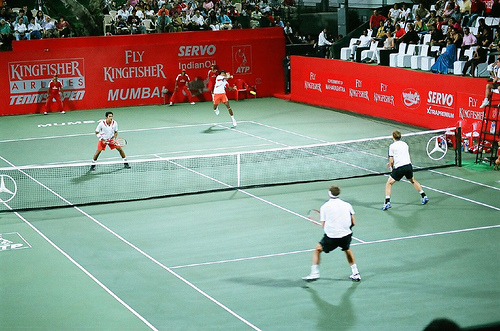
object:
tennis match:
[1, 38, 499, 327]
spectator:
[396, 24, 420, 50]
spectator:
[458, 43, 487, 78]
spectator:
[477, 18, 494, 46]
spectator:
[370, 10, 389, 35]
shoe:
[303, 265, 324, 285]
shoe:
[340, 263, 363, 282]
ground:
[392, 94, 472, 171]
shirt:
[93, 123, 120, 143]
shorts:
[321, 229, 356, 251]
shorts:
[391, 160, 416, 180]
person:
[191, 9, 209, 31]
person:
[207, 10, 220, 31]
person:
[156, 10, 171, 33]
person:
[250, 5, 263, 28]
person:
[56, 17, 70, 38]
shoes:
[298, 268, 362, 288]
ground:
[358, 165, 399, 202]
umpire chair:
[479, 57, 500, 109]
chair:
[390, 42, 407, 66]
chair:
[399, 44, 411, 66]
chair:
[407, 44, 426, 67]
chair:
[420, 46, 439, 70]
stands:
[327, 0, 498, 77]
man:
[381, 130, 429, 210]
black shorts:
[318, 232, 352, 253]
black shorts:
[389, 163, 413, 180]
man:
[90, 112, 130, 171]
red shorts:
[95, 139, 117, 150]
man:
[303, 186, 361, 285]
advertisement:
[101, 47, 168, 82]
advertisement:
[6, 54, 89, 104]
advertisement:
[176, 41, 221, 73]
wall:
[1, 23, 288, 118]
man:
[212, 69, 237, 127]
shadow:
[297, 277, 363, 324]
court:
[0, 93, 500, 327]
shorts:
[97, 137, 121, 150]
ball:
[250, 91, 256, 95]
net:
[0, 125, 465, 210]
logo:
[426, 135, 448, 161]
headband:
[327, 191, 342, 198]